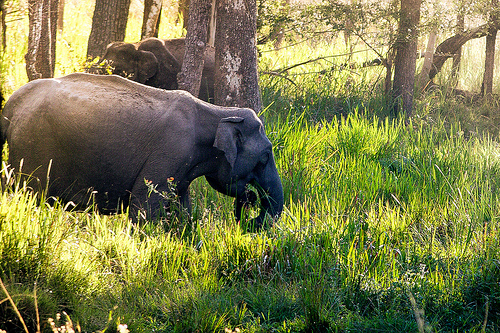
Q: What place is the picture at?
A: It is at the field.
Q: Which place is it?
A: It is a field.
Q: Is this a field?
A: Yes, it is a field.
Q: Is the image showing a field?
A: Yes, it is showing a field.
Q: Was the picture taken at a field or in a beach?
A: It was taken at a field.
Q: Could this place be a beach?
A: No, it is a field.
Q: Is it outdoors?
A: Yes, it is outdoors.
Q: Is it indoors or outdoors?
A: It is outdoors.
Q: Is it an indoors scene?
A: No, it is outdoors.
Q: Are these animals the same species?
A: Yes, all the animals are elephants.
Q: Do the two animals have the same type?
A: Yes, all the animals are elephants.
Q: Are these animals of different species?
A: No, all the animals are elephants.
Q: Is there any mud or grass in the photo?
A: Yes, there is grass.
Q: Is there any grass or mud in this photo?
A: Yes, there is grass.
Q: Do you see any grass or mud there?
A: Yes, there is grass.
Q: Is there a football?
A: No, there are no footballs.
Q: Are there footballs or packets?
A: No, there are no footballs or packets.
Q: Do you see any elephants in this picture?
A: Yes, there is an elephant.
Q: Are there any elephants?
A: Yes, there is an elephant.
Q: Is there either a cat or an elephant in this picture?
A: Yes, there is an elephant.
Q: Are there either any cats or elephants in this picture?
A: Yes, there is an elephant.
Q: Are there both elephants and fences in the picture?
A: No, there is an elephant but no fences.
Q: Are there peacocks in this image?
A: No, there are no peacocks.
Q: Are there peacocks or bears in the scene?
A: No, there are no peacocks or bears.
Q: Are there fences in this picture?
A: No, there are no fences.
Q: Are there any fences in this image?
A: No, there are no fences.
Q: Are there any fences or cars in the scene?
A: No, there are no fences or cars.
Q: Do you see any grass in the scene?
A: Yes, there is grass.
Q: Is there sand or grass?
A: Yes, there is grass.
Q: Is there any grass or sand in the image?
A: Yes, there is grass.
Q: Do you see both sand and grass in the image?
A: No, there is grass but no sand.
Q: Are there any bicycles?
A: No, there are no bicycles.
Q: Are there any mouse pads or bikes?
A: No, there are no bikes or mouse pads.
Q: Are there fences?
A: No, there are no fences.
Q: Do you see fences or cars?
A: No, there are no fences or cars.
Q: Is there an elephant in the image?
A: Yes, there is an elephant.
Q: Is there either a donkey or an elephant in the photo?
A: Yes, there is an elephant.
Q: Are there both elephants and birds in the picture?
A: No, there is an elephant but no birds.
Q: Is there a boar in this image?
A: No, there are no boars.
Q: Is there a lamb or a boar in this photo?
A: No, there are no boars or lambs.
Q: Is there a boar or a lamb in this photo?
A: No, there are no boars or lambs.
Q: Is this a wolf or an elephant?
A: This is an elephant.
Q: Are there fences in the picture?
A: No, there are no fences.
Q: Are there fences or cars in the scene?
A: No, there are no fences or cars.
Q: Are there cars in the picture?
A: No, there are no cars.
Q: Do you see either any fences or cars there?
A: No, there are no cars or fences.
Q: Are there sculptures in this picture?
A: No, there are no sculptures.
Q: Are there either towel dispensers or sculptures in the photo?
A: No, there are no sculptures or towel dispensers.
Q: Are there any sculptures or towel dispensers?
A: No, there are no sculptures or towel dispensers.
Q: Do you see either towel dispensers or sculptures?
A: No, there are no sculptures or towel dispensers.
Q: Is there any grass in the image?
A: Yes, there is grass.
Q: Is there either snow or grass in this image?
A: Yes, there is grass.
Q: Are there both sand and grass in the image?
A: No, there is grass but no sand.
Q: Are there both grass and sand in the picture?
A: No, there is grass but no sand.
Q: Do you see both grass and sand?
A: No, there is grass but no sand.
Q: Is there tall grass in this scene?
A: Yes, there is tall grass.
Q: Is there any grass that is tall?
A: Yes, there is grass that is tall.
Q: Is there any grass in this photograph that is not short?
A: Yes, there is tall grass.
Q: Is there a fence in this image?
A: No, there are no fences.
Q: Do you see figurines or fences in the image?
A: No, there are no fences or figurines.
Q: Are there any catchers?
A: No, there are no catchers.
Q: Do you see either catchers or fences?
A: No, there are no catchers or fences.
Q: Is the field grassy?
A: Yes, the field is grassy.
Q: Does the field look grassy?
A: Yes, the field is grassy.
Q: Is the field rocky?
A: No, the field is grassy.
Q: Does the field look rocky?
A: No, the field is grassy.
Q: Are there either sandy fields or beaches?
A: No, there is a field but it is grassy.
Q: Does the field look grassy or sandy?
A: The field is grassy.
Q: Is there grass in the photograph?
A: Yes, there is grass.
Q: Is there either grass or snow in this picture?
A: Yes, there is grass.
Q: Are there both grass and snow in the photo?
A: No, there is grass but no snow.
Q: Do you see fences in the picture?
A: No, there are no fences.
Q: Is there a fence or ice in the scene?
A: No, there are no fences or ice.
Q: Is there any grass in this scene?
A: Yes, there is grass.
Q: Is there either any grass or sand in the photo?
A: Yes, there is grass.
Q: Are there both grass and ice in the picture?
A: No, there is grass but no ice.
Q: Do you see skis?
A: No, there are no skis.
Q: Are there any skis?
A: No, there are no skis.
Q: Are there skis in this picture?
A: No, there are no skis.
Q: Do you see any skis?
A: No, there are no skis.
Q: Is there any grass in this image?
A: Yes, there is grass.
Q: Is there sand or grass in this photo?
A: Yes, there is grass.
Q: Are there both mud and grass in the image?
A: No, there is grass but no mud.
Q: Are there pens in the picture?
A: No, there are no pens.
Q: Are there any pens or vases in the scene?
A: No, there are no pens or vases.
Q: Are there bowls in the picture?
A: No, there are no bowls.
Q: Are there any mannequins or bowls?
A: No, there are no bowls or mannequins.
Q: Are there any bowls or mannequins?
A: No, there are no bowls or mannequins.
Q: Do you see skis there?
A: No, there are no skis.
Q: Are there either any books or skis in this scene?
A: No, there are no skis or books.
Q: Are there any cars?
A: No, there are no cars.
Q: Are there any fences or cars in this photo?
A: No, there are no cars or fences.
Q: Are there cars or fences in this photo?
A: No, there are no cars or fences.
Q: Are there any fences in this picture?
A: No, there are no fences.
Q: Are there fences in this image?
A: No, there are no fences.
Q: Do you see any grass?
A: Yes, there is grass.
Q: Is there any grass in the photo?
A: Yes, there is grass.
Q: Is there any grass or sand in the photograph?
A: Yes, there is grass.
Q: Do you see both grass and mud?
A: No, there is grass but no mud.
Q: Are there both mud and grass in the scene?
A: No, there is grass but no mud.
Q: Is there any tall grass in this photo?
A: Yes, there is tall grass.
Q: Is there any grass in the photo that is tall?
A: Yes, there is grass that is tall.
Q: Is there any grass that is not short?
A: Yes, there is tall grass.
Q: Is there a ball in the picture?
A: No, there are no balls.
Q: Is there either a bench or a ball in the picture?
A: No, there are no balls or benches.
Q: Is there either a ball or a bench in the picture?
A: No, there are no balls or benches.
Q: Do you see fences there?
A: No, there are no fences.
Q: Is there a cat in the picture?
A: No, there are no cats.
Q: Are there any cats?
A: No, there are no cats.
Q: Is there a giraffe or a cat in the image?
A: No, there are no cats or giraffes.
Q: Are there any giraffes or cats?
A: No, there are no cats or giraffes.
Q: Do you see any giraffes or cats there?
A: No, there are no cats or giraffes.